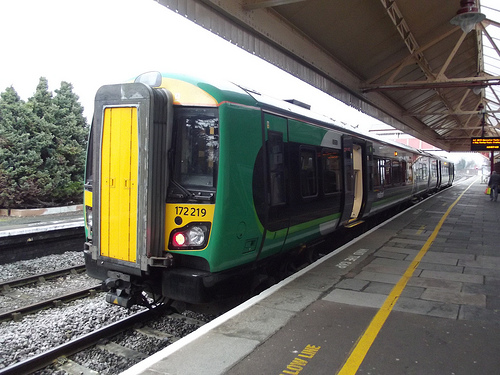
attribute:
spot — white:
[292, 348, 301, 356]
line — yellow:
[338, 178, 479, 375]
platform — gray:
[118, 181, 499, 375]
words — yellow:
[278, 342, 324, 375]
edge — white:
[115, 186, 454, 375]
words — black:
[173, 206, 209, 218]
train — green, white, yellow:
[80, 68, 455, 314]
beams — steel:
[247, 2, 499, 141]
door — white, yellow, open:
[348, 139, 365, 219]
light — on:
[176, 228, 205, 249]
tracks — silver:
[1, 261, 170, 375]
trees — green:
[1, 75, 90, 211]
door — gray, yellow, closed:
[91, 83, 175, 271]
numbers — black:
[175, 205, 208, 218]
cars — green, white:
[412, 146, 456, 203]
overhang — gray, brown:
[151, 2, 498, 153]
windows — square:
[265, 139, 403, 214]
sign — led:
[471, 139, 500, 151]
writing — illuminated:
[472, 139, 498, 152]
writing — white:
[336, 245, 370, 269]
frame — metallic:
[350, 3, 498, 141]